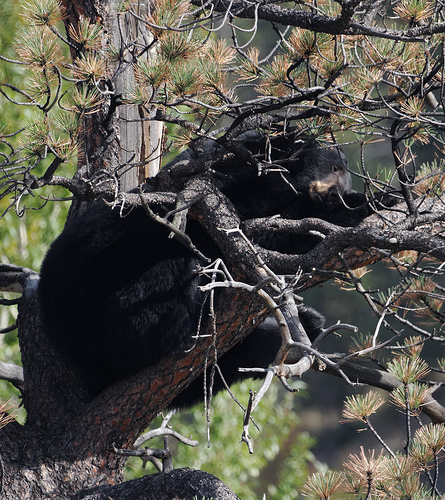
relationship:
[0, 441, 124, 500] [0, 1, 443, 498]
bark sleeping in tree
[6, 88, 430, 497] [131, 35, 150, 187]
tree has gap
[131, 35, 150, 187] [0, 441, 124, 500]
gap behind bark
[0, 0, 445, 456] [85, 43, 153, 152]
branch of tree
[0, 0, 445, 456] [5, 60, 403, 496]
branch of tree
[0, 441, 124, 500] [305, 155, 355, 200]
bark has muzzle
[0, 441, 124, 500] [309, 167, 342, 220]
bark has mouth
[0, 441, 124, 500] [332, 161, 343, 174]
bark has eye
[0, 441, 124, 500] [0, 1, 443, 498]
bark laying on tree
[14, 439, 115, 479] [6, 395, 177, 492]
bark on side of trunk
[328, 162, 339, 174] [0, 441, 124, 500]
eye on bark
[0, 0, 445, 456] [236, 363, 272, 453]
branch shaped like seven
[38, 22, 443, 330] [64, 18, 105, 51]
branch behind pine needles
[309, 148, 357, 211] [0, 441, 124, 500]
face of bark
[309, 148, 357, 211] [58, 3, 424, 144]
face in tree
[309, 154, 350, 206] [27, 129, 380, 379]
face of animal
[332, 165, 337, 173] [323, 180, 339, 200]
eye above nose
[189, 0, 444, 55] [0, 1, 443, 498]
branches on tree